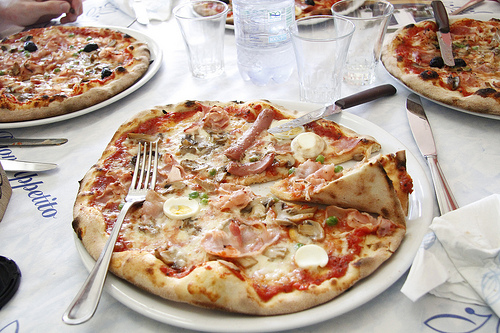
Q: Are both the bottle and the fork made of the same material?
A: No, the bottle is made of plastic and the fork is made of metal.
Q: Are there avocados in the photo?
A: No, there are no avocados.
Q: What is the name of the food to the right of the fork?
A: The food is an egg.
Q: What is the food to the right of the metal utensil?
A: The food is an egg.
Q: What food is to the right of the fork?
A: The food is an egg.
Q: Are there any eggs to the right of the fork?
A: Yes, there is an egg to the right of the fork.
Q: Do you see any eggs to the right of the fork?
A: Yes, there is an egg to the right of the fork.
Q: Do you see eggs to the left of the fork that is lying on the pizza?
A: No, the egg is to the right of the fork.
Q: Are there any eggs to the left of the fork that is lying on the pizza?
A: No, the egg is to the right of the fork.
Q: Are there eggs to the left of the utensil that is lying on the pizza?
A: No, the egg is to the right of the fork.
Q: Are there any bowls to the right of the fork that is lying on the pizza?
A: No, there is an egg to the right of the fork.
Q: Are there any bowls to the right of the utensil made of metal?
A: No, there is an egg to the right of the fork.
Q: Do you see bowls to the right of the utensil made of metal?
A: No, there is an egg to the right of the fork.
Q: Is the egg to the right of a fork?
A: Yes, the egg is to the right of a fork.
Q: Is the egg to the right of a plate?
A: No, the egg is to the right of a fork.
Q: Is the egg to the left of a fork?
A: No, the egg is to the right of a fork.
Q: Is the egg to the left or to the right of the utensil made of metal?
A: The egg is to the right of the fork.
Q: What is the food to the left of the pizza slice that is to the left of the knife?
A: The food is an egg.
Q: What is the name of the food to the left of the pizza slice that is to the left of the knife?
A: The food is an egg.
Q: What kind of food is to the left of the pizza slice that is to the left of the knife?
A: The food is an egg.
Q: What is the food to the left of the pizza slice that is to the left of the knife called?
A: The food is an egg.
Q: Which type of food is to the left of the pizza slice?
A: The food is an egg.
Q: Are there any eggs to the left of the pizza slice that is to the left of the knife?
A: Yes, there is an egg to the left of the pizza slice.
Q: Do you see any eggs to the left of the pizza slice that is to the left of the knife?
A: Yes, there is an egg to the left of the pizza slice.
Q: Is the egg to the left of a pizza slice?
A: Yes, the egg is to the left of a pizza slice.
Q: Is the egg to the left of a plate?
A: No, the egg is to the left of a pizza slice.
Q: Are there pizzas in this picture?
A: Yes, there is a pizza.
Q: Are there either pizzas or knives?
A: Yes, there is a pizza.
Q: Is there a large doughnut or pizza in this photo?
A: Yes, there is a large pizza.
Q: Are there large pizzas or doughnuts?
A: Yes, there is a large pizza.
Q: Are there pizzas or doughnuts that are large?
A: Yes, the pizza is large.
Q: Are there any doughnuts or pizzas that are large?
A: Yes, the pizza is large.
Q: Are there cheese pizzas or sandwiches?
A: Yes, there is a cheese pizza.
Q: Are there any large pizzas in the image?
A: Yes, there is a large pizza.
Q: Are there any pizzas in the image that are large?
A: Yes, there is a pizza that is large.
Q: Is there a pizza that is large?
A: Yes, there is a pizza that is large.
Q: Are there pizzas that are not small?
A: Yes, there is a large pizza.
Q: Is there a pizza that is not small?
A: Yes, there is a large pizza.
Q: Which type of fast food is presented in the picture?
A: The fast food is a pizza.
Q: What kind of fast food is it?
A: The food is a pizza.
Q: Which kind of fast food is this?
A: That is a pizza.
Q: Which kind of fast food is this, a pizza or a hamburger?
A: That is a pizza.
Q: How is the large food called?
A: The food is a pizza.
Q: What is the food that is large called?
A: The food is a pizza.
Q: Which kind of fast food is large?
A: The fast food is a pizza.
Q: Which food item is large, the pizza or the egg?
A: The pizza is large.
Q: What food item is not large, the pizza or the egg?
A: The egg is not large.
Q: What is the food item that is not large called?
A: The food item is an egg.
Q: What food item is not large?
A: The food item is an egg.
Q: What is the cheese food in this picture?
A: The food is a pizza.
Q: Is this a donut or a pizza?
A: This is a pizza.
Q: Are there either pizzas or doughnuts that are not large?
A: No, there is a pizza but it is large.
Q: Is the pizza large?
A: Yes, the pizza is large.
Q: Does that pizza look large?
A: Yes, the pizza is large.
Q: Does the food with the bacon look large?
A: Yes, the pizza is large.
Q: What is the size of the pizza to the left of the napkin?
A: The pizza is large.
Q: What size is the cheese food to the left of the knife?
A: The pizza is large.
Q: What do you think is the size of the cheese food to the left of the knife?
A: The pizza is large.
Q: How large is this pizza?
A: The pizza is large.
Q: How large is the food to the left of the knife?
A: The pizza is large.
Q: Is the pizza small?
A: No, the pizza is large.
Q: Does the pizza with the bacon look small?
A: No, the pizza is large.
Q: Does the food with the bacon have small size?
A: No, the pizza is large.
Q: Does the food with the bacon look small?
A: No, the pizza is large.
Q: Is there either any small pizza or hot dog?
A: No, there is a pizza but it is large.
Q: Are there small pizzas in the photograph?
A: No, there is a pizza but it is large.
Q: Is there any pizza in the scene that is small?
A: No, there is a pizza but it is large.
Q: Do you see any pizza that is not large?
A: No, there is a pizza but it is large.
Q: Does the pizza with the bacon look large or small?
A: The pizza is large.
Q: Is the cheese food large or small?
A: The pizza is large.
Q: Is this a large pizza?
A: Yes, this is a large pizza.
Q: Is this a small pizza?
A: No, this is a large pizza.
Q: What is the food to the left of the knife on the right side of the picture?
A: The food is a pizza.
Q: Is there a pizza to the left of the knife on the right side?
A: Yes, there is a pizza to the left of the knife.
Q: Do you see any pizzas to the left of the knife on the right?
A: Yes, there is a pizza to the left of the knife.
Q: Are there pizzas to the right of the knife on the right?
A: No, the pizza is to the left of the knife.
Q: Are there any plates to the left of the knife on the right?
A: No, there is a pizza to the left of the knife.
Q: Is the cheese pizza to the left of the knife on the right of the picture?
A: Yes, the pizza is to the left of the knife.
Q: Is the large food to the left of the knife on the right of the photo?
A: Yes, the pizza is to the left of the knife.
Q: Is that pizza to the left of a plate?
A: No, the pizza is to the left of the knife.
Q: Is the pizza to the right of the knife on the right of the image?
A: No, the pizza is to the left of the knife.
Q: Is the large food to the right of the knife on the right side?
A: No, the pizza is to the left of the knife.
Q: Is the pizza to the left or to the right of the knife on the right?
A: The pizza is to the left of the knife.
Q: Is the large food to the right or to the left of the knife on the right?
A: The pizza is to the left of the knife.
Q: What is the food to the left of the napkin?
A: The food is a pizza.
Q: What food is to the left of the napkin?
A: The food is a pizza.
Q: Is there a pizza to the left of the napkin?
A: Yes, there is a pizza to the left of the napkin.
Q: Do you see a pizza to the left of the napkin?
A: Yes, there is a pizza to the left of the napkin.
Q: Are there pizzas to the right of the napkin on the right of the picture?
A: No, the pizza is to the left of the napkin.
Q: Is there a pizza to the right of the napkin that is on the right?
A: No, the pizza is to the left of the napkin.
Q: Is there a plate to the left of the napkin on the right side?
A: No, there is a pizza to the left of the napkin.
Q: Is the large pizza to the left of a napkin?
A: Yes, the pizza is to the left of a napkin.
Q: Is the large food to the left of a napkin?
A: Yes, the pizza is to the left of a napkin.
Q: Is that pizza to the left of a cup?
A: No, the pizza is to the left of a napkin.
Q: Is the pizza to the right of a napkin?
A: No, the pizza is to the left of a napkin.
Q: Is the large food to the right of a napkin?
A: No, the pizza is to the left of a napkin.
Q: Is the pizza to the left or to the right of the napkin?
A: The pizza is to the left of the napkin.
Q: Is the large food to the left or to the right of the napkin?
A: The pizza is to the left of the napkin.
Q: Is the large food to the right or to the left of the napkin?
A: The pizza is to the left of the napkin.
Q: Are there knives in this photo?
A: Yes, there is a knife.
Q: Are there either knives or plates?
A: Yes, there is a knife.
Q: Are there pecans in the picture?
A: No, there are no pecans.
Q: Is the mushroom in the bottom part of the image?
A: Yes, the mushroom is in the bottom of the image.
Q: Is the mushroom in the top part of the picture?
A: No, the mushroom is in the bottom of the image.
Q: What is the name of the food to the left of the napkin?
A: The food is a mushroom.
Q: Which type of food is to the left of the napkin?
A: The food is a mushroom.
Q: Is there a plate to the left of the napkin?
A: No, there is a mushroom to the left of the napkin.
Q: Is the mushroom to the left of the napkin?
A: Yes, the mushroom is to the left of the napkin.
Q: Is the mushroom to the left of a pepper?
A: No, the mushroom is to the left of the napkin.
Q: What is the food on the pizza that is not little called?
A: The food is a mushroom.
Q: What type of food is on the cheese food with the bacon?
A: The food is a mushroom.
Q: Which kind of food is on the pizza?
A: The food is a mushroom.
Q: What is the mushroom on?
A: The mushroom is on the pizza.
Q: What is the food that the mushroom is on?
A: The food is a pizza.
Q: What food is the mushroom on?
A: The mushroom is on the pizza.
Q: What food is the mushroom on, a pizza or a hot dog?
A: The mushroom is on a pizza.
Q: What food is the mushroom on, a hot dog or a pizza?
A: The mushroom is on a pizza.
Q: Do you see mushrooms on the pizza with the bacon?
A: Yes, there is a mushroom on the pizza.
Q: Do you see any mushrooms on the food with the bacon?
A: Yes, there is a mushroom on the pizza.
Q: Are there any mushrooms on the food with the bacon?
A: Yes, there is a mushroom on the pizza.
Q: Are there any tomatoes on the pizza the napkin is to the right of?
A: No, there is a mushroom on the pizza.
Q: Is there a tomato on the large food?
A: No, there is a mushroom on the pizza.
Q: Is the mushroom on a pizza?
A: Yes, the mushroom is on a pizza.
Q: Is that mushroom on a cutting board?
A: No, the mushroom is on a pizza.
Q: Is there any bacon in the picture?
A: Yes, there is bacon.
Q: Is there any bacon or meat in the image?
A: Yes, there is bacon.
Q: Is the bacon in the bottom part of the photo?
A: Yes, the bacon is in the bottom of the image.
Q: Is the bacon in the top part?
A: No, the bacon is in the bottom of the image.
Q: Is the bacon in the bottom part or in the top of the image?
A: The bacon is in the bottom of the image.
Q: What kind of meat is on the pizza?
A: The meat is bacon.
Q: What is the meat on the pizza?
A: The meat is bacon.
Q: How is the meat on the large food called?
A: The meat is bacon.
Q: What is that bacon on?
A: The bacon is on the pizza.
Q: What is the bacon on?
A: The bacon is on the pizza.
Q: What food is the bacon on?
A: The bacon is on the pizza.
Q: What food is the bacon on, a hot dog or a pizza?
A: The bacon is on a pizza.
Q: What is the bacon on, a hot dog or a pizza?
A: The bacon is on a pizza.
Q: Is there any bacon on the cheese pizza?
A: Yes, there is bacon on the pizza.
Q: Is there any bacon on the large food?
A: Yes, there is bacon on the pizza.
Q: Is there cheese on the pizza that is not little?
A: No, there is bacon on the pizza.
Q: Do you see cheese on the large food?
A: No, there is bacon on the pizza.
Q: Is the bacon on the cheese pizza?
A: Yes, the bacon is on the pizza.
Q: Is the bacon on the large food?
A: Yes, the bacon is on the pizza.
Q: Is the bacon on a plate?
A: No, the bacon is on the pizza.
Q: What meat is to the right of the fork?
A: The meat is bacon.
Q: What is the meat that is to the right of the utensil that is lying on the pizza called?
A: The meat is bacon.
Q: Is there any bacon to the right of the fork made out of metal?
A: Yes, there is bacon to the right of the fork.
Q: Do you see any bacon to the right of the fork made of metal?
A: Yes, there is bacon to the right of the fork.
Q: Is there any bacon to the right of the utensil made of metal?
A: Yes, there is bacon to the right of the fork.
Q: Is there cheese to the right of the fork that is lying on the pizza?
A: No, there is bacon to the right of the fork.